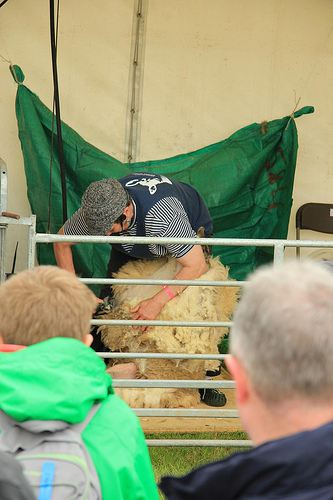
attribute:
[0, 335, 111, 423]
hood — green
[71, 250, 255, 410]
sheep — very woolly, sheared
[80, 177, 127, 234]
hat — gray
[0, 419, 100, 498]
backpack — gray